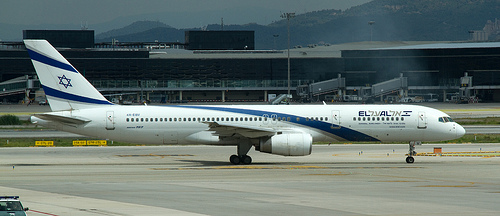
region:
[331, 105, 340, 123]
the door of a plane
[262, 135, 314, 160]
the engine of a plane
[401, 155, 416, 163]
the front wheel of a plane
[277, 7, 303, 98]
a tall light pole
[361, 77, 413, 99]
a long gray gate tunnel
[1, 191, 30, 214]
part of a vehicle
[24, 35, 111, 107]
the tail of a plane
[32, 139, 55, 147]
a yellow runway sign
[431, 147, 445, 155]
a small runway sign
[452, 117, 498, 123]
a small section of green grass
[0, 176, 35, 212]
support vehicle on runway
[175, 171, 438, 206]
an airport's tarmac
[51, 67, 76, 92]
The Star of David, symbol of Judaism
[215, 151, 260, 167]
back landing wheels of an airplane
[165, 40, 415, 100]
runway side of airport terminal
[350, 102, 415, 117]
logo/description of airline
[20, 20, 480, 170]
an airplane taxing into position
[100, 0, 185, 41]
mountains in the distance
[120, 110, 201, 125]
long row of windows in the main cabin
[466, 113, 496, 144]
patches of grass on the runway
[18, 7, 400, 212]
a plane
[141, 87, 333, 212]
a plane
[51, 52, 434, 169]
a plane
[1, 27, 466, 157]
White and blue airplane.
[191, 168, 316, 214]
The roadway.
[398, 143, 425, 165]
Airplane tires.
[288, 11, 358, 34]
Mountains in the background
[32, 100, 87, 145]
The wing of the airplane.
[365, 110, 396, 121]
Windows on the airplane.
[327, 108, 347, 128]
Door on the airplane.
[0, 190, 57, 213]
Cop car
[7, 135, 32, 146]
Grass.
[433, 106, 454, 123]
Windshield of the airplane.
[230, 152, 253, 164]
Wheels under a plane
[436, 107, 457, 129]
Windshield in the front of a plane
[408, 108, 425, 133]
Door on a plane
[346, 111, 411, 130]
Windows on a plane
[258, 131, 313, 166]
Jet on a plane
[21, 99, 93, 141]
Tail on a plane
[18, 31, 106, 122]
Blue and white tail on a plane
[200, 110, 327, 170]
White wing on a plane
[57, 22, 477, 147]
Silver and gray airport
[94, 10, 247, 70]
Hills by and airport